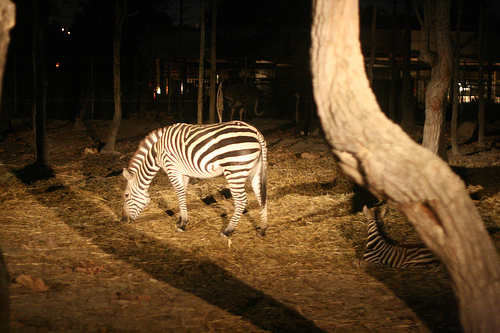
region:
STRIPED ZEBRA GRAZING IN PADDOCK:
[117, 112, 281, 241]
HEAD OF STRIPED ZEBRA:
[112, 167, 149, 223]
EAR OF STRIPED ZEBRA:
[119, 189, 133, 199]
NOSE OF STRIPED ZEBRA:
[122, 211, 130, 221]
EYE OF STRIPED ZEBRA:
[118, 189, 128, 199]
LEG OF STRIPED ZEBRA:
[165, 171, 196, 231]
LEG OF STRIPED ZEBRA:
[224, 174, 246, 241]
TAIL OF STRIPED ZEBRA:
[257, 136, 272, 217]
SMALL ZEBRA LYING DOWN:
[348, 196, 440, 289]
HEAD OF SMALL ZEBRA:
[359, 199, 389, 232]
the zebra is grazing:
[79, 114, 256, 329]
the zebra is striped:
[90, 88, 335, 315]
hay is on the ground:
[47, 195, 217, 331]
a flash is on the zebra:
[96, 45, 255, 288]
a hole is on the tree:
[369, 162, 488, 294]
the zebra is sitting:
[329, 181, 406, 284]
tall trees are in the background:
[43, 52, 430, 154]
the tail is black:
[252, 151, 299, 267]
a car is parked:
[140, 33, 266, 118]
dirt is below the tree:
[62, 126, 191, 243]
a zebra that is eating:
[66, 129, 286, 249]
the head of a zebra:
[113, 158, 154, 216]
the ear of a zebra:
[120, 158, 136, 176]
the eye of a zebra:
[114, 190, 144, 199]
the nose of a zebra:
[115, 206, 141, 224]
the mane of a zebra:
[135, 133, 155, 159]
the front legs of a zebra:
[154, 171, 204, 242]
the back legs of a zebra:
[219, 170, 290, 227]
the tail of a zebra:
[251, 139, 284, 204]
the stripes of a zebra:
[195, 126, 242, 162]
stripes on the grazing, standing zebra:
[123, 121, 270, 238]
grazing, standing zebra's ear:
[120, 165, 132, 180]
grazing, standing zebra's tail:
[258, 136, 268, 205]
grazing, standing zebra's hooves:
[177, 216, 269, 237]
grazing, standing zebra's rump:
[215, 118, 262, 177]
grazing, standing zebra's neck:
[131, 126, 160, 185]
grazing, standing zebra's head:
[122, 166, 148, 218]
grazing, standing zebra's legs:
[164, 171, 280, 220]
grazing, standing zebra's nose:
[121, 208, 132, 221]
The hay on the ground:
[47, 236, 323, 276]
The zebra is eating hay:
[103, 112, 281, 247]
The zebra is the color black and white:
[147, 118, 246, 174]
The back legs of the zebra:
[219, 166, 271, 245]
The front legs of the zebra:
[166, 173, 194, 232]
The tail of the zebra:
[253, 130, 270, 212]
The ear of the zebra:
[119, 161, 136, 186]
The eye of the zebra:
[119, 185, 134, 204]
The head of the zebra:
[116, 168, 156, 225]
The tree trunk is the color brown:
[298, 5, 498, 330]